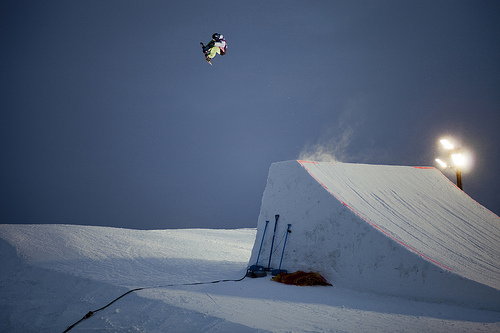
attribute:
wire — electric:
[56, 278, 244, 331]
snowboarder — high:
[205, 29, 232, 58]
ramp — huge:
[244, 152, 481, 308]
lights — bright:
[426, 131, 477, 171]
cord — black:
[119, 285, 182, 301]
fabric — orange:
[279, 268, 317, 288]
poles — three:
[256, 213, 296, 273]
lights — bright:
[427, 138, 473, 175]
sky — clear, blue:
[290, 32, 354, 71]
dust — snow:
[305, 104, 364, 164]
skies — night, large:
[205, 39, 226, 74]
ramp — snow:
[313, 234, 361, 262]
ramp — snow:
[321, 162, 370, 257]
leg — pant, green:
[200, 57, 220, 66]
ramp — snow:
[315, 166, 362, 237]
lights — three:
[413, 137, 478, 174]